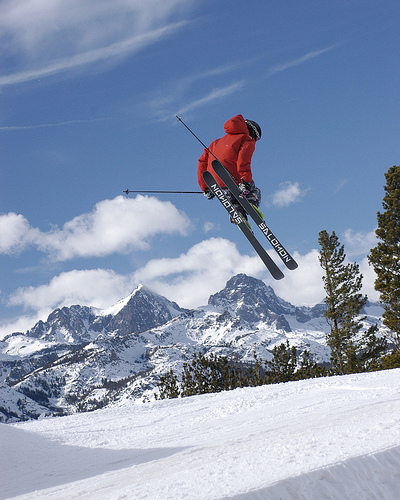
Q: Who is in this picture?
A: A skier.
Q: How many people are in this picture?
A: One.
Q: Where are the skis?
A: On the skier's feet.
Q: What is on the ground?
A: Snow.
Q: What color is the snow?
A: White.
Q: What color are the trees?
A: Green.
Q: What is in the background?
A: Mountains.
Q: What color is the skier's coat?
A: Red.